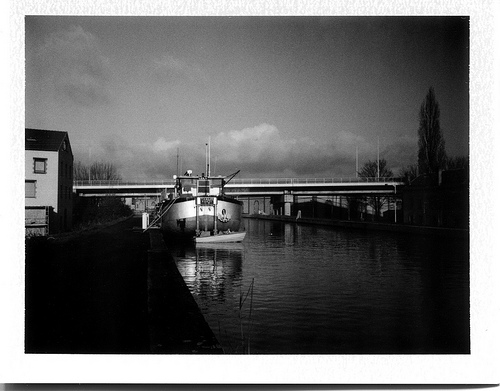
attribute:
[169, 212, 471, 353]
water — calm 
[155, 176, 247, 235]
boat — docked 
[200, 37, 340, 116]
sky — cloudy , hazy 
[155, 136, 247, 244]
ship — large 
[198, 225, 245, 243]
boat — smaller 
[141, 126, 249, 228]
boat — larger 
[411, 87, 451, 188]
tree — tall 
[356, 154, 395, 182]
tree — large 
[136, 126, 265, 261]
ship — large 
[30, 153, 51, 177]
window — small , square 